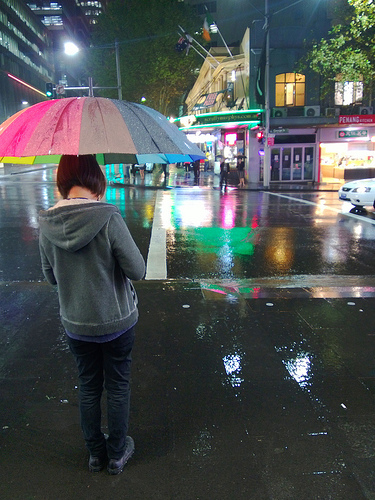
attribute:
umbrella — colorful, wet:
[4, 93, 206, 173]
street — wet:
[172, 192, 322, 319]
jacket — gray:
[25, 208, 160, 330]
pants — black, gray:
[63, 336, 137, 459]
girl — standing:
[21, 154, 148, 487]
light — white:
[55, 37, 88, 63]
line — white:
[137, 181, 184, 276]